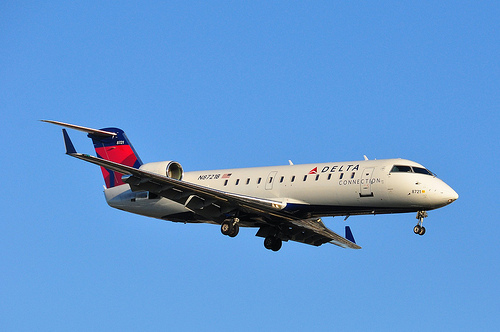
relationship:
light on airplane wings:
[137, 166, 152, 180] [66, 143, 305, 240]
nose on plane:
[390, 150, 464, 219] [61, 76, 466, 246]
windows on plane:
[220, 174, 371, 185] [194, 157, 449, 224]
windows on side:
[220, 174, 371, 185] [105, 158, 443, 206]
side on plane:
[105, 158, 443, 206] [194, 157, 449, 224]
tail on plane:
[38, 114, 144, 189] [30, 101, 494, 319]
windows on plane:
[223, 172, 357, 187] [76, 111, 481, 248]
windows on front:
[223, 172, 357, 187] [289, 147, 459, 247]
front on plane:
[289, 147, 459, 247] [76, 111, 481, 248]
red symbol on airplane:
[307, 164, 319, 178] [36, 118, 459, 251]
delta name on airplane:
[317, 163, 365, 173] [36, 118, 459, 251]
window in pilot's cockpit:
[391, 160, 441, 179] [368, 139, 479, 196]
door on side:
[355, 166, 376, 197] [123, 169, 443, 200]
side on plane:
[123, 169, 443, 200] [32, 105, 484, 215]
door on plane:
[355, 166, 376, 197] [32, 105, 484, 215]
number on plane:
[196, 171, 228, 185] [73, 126, 477, 246]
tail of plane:
[38, 114, 144, 189] [35, 101, 465, 279]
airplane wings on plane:
[60, 128, 312, 229] [36, 95, 437, 270]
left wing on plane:
[295, 216, 363, 250] [36, 95, 437, 270]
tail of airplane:
[38, 114, 144, 189] [37, 117, 459, 251]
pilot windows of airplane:
[391, 163, 432, 175] [37, 117, 459, 251]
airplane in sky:
[36, 118, 459, 251] [4, 2, 484, 328]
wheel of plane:
[218, 215, 240, 236] [34, 115, 461, 252]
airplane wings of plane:
[60, 128, 312, 229] [34, 115, 461, 252]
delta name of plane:
[320, 162, 360, 172] [31, 63, 485, 272]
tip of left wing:
[343, 225, 357, 248] [314, 223, 361, 250]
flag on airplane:
[219, 170, 234, 177] [37, 117, 459, 251]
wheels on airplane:
[217, 215, 239, 237] [37, 117, 459, 251]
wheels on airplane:
[262, 233, 283, 251] [37, 117, 459, 251]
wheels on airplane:
[411, 223, 427, 235] [37, 117, 459, 251]